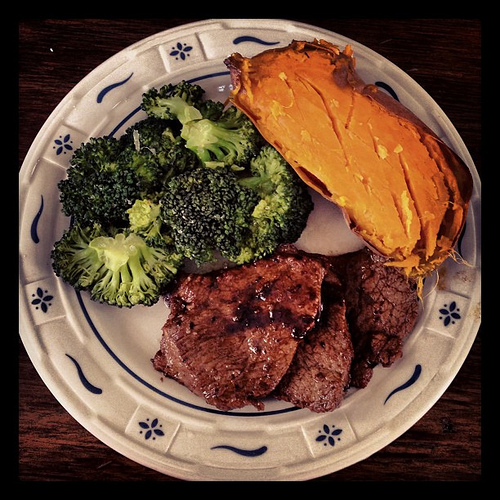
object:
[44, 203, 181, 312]
broccoli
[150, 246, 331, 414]
meat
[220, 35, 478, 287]
sweet potato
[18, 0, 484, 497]
table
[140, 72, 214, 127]
food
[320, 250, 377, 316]
sauce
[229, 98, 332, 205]
skin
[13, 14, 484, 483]
plate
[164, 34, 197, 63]
flower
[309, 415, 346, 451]
flower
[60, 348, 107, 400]
blue pattern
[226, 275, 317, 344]
gravy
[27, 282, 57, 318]
star